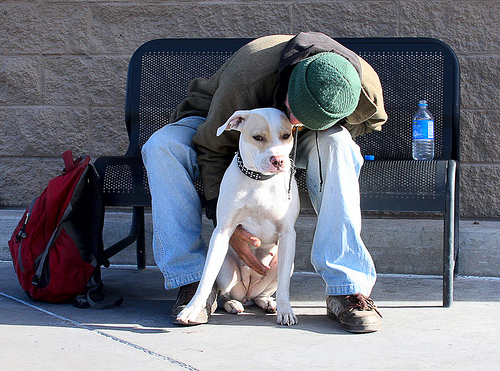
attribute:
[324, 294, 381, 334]
shoe — brown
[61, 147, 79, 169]
handle — red 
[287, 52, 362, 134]
hat — green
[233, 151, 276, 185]
studs — silver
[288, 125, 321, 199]
draw stings — hanging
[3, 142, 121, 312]
backpack — red, leaning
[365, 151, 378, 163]
top — blue